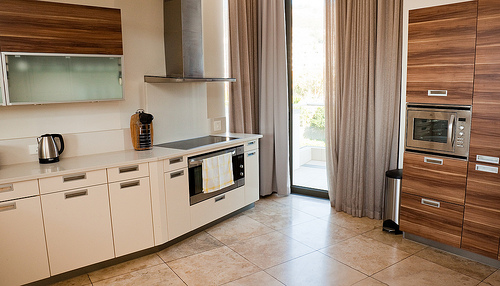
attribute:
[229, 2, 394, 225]
curtains — beige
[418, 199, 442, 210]
handle — Silver 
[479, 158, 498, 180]
handle — Silver 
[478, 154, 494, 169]
handle — Silver 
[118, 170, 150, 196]
handle — Silver 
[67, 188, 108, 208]
handle — Silver 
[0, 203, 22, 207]
handle — Silver 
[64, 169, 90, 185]
handle — Silver 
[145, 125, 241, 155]
stove top — black 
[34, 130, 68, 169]
kettle — silver 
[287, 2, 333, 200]
glass door — tall 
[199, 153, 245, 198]
towel — white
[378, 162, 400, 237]
trash bin — for trash, black, silver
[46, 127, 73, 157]
handle — black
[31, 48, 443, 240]
kitchen — modern, white, brown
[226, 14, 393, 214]
draperies — beige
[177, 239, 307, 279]
tiles — large, square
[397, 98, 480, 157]
microwave — silver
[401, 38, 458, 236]
drawers — wooden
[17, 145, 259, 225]
counter — long, white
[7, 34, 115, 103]
cabinets — wood, frosted, glass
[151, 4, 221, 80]
pipe — large, metal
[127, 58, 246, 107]
panel — thin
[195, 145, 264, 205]
towel — dish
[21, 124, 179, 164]
appliances — silver, yellow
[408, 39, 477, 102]
drawer — wood, paneled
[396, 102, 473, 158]
microwave oven — small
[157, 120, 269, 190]
stove top — metal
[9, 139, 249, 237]
counter — cream, colored, kitchen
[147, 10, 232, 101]
duct — for ventilation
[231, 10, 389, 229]
drapes — long, sliding, for window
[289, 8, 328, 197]
door — full size, glass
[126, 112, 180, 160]
rack — kitchen, utensil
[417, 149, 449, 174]
cabinet handle — silver , colored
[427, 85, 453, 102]
cabinet handle — colored, silver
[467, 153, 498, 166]
handle — silver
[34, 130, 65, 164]
pot — silver, coffee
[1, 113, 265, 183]
counter — kitchen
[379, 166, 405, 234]
can — trash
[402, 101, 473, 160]
microwave — silver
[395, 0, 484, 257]
wall — wooden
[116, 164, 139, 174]
handle — silver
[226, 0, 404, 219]
curtains — beige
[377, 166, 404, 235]
can — silver, trash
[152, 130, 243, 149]
top — electric, stove, range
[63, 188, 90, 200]
handle — silver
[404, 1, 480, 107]
door — wooden, cabinet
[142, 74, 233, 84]
shelf — metal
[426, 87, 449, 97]
handle — metal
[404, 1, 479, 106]
cabinet — wooden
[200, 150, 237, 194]
cloth — dish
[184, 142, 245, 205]
door — oven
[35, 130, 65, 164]
kettle — stainless steel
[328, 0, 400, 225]
drapes — long, beige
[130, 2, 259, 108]
exhaust — silver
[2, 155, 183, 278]
cabinets — beige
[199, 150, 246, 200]
hand towel — white, yellow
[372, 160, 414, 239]
trash can — silver, black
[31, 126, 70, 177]
kettle — silver, Black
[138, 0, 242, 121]
vent — silver